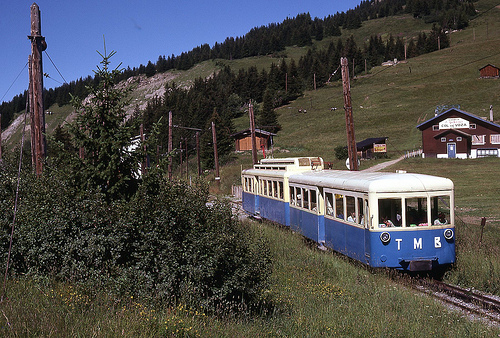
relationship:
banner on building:
[437, 117, 470, 129] [417, 104, 498, 159]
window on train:
[333, 192, 345, 221] [241, 155, 457, 271]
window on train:
[309, 190, 317, 214] [241, 155, 457, 271]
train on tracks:
[241, 155, 457, 271] [403, 275, 498, 323]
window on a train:
[355, 176, 440, 278] [281, 133, 490, 302]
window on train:
[405, 195, 427, 226] [241, 155, 457, 271]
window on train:
[430, 195, 450, 224] [241, 155, 457, 271]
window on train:
[377, 198, 402, 226] [241, 155, 457, 271]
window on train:
[339, 192, 364, 227] [232, 146, 497, 282]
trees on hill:
[0, 17, 447, 332] [4, 39, 496, 204]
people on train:
[384, 202, 440, 227] [227, 146, 474, 289]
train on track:
[241, 155, 457, 271] [415, 276, 498, 321]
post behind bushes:
[162, 111, 227, 181] [13, 40, 299, 310]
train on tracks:
[241, 155, 457, 271] [397, 272, 499, 326]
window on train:
[286, 186, 295, 208] [238, 167, 458, 270]